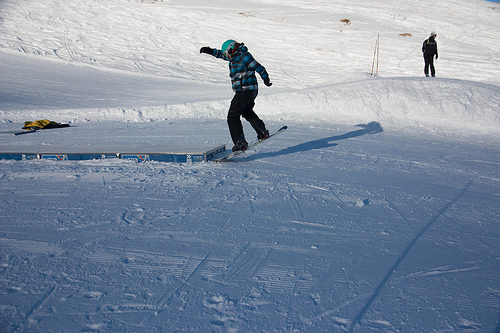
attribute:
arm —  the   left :
[197, 44, 229, 64]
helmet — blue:
[211, 33, 239, 63]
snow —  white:
[0, 158, 500, 331]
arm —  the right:
[197, 42, 231, 62]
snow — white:
[274, 7, 411, 112]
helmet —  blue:
[220, 37, 242, 57]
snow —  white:
[270, 80, 497, 137]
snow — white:
[261, 183, 382, 283]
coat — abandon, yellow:
[20, 118, 69, 130]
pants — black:
[223, 90, 265, 143]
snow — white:
[21, 27, 476, 329]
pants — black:
[200, 93, 279, 142]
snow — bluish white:
[186, 204, 335, 285]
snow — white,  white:
[12, 4, 488, 331]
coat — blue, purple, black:
[208, 39, 273, 99]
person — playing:
[183, 70, 293, 149]